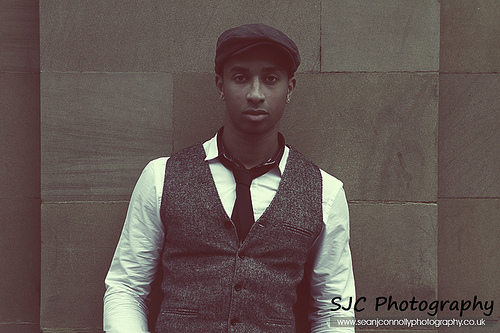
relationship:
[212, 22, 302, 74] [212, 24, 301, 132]
hat on head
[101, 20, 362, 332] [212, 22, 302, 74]
man wearing hat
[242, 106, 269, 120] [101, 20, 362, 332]
mouth of person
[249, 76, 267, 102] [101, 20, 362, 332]
nose of person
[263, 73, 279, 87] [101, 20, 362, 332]
eye of person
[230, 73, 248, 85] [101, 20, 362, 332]
eye of person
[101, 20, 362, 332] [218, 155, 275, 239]
person wearing tie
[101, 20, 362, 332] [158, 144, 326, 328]
man wearing vest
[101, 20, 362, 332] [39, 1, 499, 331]
man next to wall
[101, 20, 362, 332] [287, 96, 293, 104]
man wearing earring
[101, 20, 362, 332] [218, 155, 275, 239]
man wearing tie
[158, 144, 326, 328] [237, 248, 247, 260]
vest has button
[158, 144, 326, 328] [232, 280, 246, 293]
vest has button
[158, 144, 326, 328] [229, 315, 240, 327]
vest has button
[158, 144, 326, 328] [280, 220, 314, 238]
vest has pocket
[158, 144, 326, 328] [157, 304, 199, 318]
vest has pocket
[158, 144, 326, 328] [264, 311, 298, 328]
vest has pocket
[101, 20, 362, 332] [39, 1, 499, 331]
man leaning against wall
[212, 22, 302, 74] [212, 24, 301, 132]
cap on head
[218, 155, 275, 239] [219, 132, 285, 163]
tie at neck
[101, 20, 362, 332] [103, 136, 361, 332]
man wearing shirt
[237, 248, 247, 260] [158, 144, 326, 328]
button on vest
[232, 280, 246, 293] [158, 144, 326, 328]
button on vest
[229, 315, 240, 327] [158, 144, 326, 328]
button on vest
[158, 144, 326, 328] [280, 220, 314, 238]
vest with pocket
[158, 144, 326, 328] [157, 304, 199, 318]
vest with pocket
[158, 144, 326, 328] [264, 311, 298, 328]
vest with pocket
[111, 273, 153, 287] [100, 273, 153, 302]
wrinkle side of elbow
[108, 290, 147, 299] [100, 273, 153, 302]
wrinkle side of elbow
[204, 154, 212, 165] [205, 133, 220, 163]
tip of collar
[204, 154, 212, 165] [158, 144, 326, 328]
tip over vest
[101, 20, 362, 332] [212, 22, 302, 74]
man wearing cap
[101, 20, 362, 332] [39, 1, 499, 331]
man front of wall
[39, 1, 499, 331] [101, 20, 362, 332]
wall behind man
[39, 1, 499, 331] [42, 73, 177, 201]
wall has block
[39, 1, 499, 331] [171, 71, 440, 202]
wall has block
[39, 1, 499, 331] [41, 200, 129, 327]
wall has block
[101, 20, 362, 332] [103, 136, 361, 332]
man has shirt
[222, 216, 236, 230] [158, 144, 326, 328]
button on vest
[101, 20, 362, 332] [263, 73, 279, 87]
man has eye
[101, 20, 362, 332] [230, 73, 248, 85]
man has eye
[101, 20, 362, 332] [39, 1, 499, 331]
man against wall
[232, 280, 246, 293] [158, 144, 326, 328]
button of vest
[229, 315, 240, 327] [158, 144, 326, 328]
button of vest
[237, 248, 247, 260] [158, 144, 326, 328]
button of vest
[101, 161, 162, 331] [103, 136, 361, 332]
sleeve of shirt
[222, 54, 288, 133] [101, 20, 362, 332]
face of man